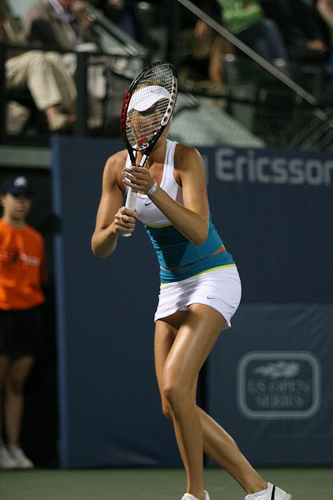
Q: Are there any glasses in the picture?
A: No, there are no glasses.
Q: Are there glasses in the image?
A: No, there are no glasses.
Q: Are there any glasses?
A: No, there are no glasses.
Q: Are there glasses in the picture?
A: No, there are no glasses.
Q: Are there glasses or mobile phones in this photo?
A: No, there are no glasses or mobile phones.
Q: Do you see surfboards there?
A: No, there are no surfboards.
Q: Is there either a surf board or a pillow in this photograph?
A: No, there are no surfboards or pillows.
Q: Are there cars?
A: No, there are no cars.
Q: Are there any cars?
A: No, there are no cars.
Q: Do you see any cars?
A: No, there are no cars.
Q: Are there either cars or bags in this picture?
A: No, there are no cars or bags.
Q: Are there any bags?
A: No, there are no bags.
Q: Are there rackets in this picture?
A: Yes, there is a racket.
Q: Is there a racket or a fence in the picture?
A: Yes, there is a racket.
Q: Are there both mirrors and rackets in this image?
A: No, there is a racket but no mirrors.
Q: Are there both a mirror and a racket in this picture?
A: No, there is a racket but no mirrors.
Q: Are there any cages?
A: No, there are no cages.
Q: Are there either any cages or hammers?
A: No, there are no cages or hammers.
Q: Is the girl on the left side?
A: Yes, the girl is on the left of the image.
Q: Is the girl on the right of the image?
A: No, the girl is on the left of the image.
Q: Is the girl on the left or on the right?
A: The girl is on the left of the image.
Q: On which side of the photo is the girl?
A: The girl is on the left of the image.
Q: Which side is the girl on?
A: The girl is on the left of the image.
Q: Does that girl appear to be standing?
A: Yes, the girl is standing.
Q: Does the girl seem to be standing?
A: Yes, the girl is standing.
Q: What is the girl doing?
A: The girl is standing.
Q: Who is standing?
A: The girl is standing.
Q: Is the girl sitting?
A: No, the girl is standing.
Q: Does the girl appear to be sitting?
A: No, the girl is standing.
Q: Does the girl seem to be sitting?
A: No, the girl is standing.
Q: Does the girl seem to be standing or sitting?
A: The girl is standing.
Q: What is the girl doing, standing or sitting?
A: The girl is standing.